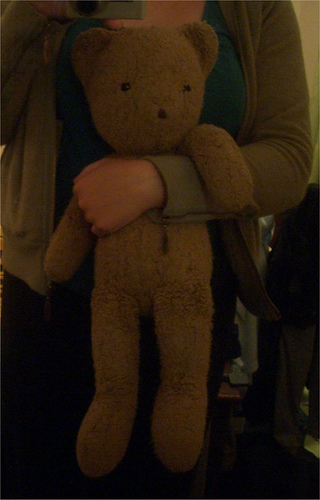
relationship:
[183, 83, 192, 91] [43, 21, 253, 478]
black eye on bear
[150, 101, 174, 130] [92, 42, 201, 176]
nose on face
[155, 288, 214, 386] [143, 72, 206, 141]
leg on bear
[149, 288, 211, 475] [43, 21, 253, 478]
leg of bear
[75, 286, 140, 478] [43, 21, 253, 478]
leg of bear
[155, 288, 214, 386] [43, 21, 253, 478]
leg of bear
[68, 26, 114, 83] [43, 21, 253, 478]
ear of bear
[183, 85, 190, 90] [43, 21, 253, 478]
black eye of bear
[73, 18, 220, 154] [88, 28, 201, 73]
head of bear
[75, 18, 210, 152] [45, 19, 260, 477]
head of bear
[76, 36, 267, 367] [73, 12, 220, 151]
bear has head